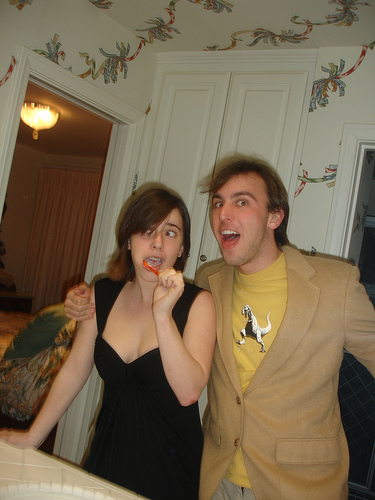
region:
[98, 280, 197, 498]
the dress is black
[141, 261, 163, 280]
the toothbrush is orange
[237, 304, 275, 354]
dinosaur is on the shirt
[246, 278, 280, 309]
the tshirt is yellow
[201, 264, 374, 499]
the suit is brown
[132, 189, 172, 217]
the hair is brown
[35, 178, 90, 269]
the curtain is orange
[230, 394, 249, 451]
the buttons are orange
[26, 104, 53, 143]
light is on the ceiling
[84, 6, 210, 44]
graphics are on the ceiling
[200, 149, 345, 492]
A woman in a picture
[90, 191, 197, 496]
A woman in a picture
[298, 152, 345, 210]
A flower pattern wall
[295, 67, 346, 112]
A flower pattern wall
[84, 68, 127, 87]
A flower pattern wall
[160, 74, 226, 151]
A white wood wall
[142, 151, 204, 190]
A white wood wall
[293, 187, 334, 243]
A white wood wall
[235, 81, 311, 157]
A white wood wall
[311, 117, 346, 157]
A white wood wall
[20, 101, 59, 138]
the ceiling light fixture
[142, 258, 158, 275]
the toothbrush in the woman's mouth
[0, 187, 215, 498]
the woman brushing her teeth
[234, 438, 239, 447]
the button on the man's jacket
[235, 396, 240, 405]
the button on the man's jacket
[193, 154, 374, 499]
the man standing with the woman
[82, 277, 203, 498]
the black dress on the woman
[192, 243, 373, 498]
the jacket on the man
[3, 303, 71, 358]
the pillow on the bed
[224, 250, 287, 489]
the shirt on the man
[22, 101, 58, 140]
A lamp hanging from the ceiling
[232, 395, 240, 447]
Buttons on the blazer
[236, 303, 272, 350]
A dinosaur on the shirt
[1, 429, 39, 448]
The right hand of the woman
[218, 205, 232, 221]
The nose of the man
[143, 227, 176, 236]
The eyes of the woman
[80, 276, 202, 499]
The woman is wearing a black dress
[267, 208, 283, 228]
The left ear of the man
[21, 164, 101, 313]
Curtains on the window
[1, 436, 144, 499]
The counter next to the people